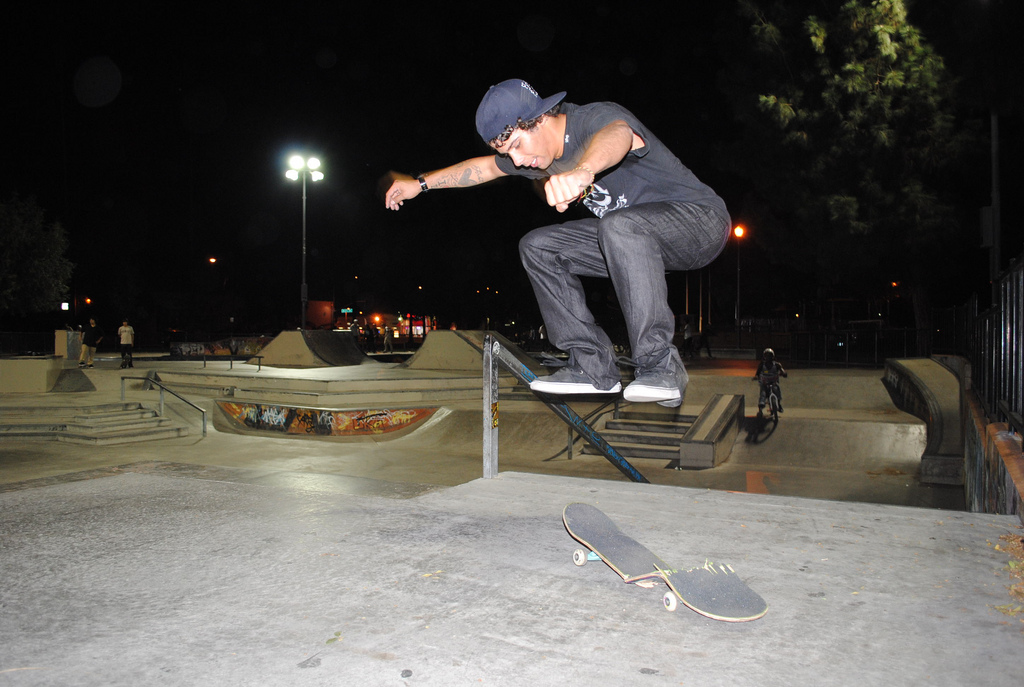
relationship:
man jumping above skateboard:
[380, 72, 735, 412] [557, 495, 771, 627]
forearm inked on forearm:
[422, 155, 498, 189] [410, 154, 499, 193]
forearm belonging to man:
[410, 154, 499, 193] [380, 72, 735, 412]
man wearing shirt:
[380, 72, 735, 412] [491, 96, 720, 222]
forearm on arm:
[422, 155, 498, 189] [343, 124, 555, 230]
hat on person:
[459, 67, 570, 124] [360, 102, 857, 452]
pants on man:
[498, 190, 816, 396] [384, 79, 734, 403]